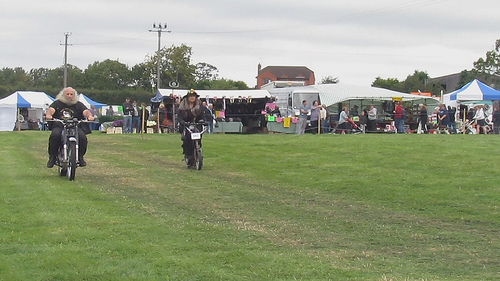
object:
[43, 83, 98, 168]
man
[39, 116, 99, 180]
motorcycle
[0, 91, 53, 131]
tent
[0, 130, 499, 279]
grass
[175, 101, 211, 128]
jacket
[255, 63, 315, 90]
building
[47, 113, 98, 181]
bike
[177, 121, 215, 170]
bike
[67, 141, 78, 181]
wheel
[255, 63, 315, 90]
house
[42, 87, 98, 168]
person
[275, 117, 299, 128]
fabric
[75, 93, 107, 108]
tent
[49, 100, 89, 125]
t shirt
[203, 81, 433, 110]
tents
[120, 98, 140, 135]
men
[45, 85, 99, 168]
motorist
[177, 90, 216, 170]
motorist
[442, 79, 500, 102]
tent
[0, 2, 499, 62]
sky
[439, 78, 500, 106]
umbrella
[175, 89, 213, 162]
person